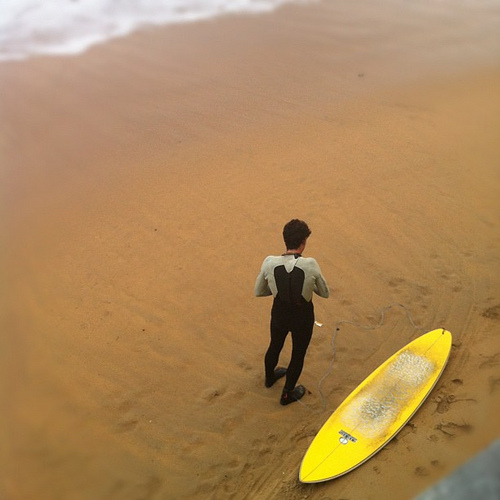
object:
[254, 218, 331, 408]
person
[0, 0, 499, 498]
sand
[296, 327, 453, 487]
surfboard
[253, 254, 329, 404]
wetsuit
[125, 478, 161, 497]
footprints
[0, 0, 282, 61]
water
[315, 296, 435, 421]
cord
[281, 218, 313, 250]
hair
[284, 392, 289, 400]
spot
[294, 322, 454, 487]
stripe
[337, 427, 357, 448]
logo